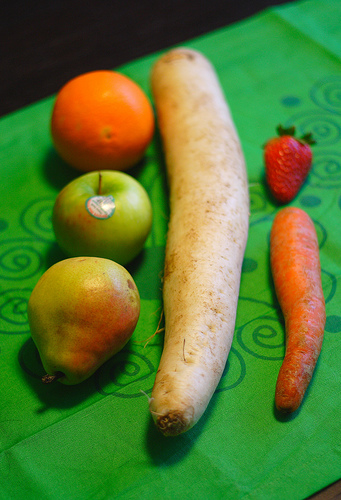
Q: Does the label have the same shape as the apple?
A: Yes, both the label and the apple are round.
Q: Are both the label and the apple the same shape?
A: Yes, both the label and the apple are round.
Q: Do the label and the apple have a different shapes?
A: No, both the label and the apple are round.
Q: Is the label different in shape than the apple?
A: No, both the label and the apple are round.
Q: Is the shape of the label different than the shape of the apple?
A: No, both the label and the apple are round.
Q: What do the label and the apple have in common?
A: The shape, both the label and the apple are round.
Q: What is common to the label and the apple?
A: The shape, both the label and the apple are round.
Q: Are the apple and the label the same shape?
A: Yes, both the apple and the label are round.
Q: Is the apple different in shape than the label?
A: No, both the apple and the label are round.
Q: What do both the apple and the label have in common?
A: The shape, both the apple and the label are round.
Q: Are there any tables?
A: Yes, there is a table.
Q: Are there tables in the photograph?
A: Yes, there is a table.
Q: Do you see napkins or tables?
A: Yes, there is a table.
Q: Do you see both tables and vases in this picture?
A: No, there is a table but no vases.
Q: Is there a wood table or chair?
A: Yes, there is a wood table.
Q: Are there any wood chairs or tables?
A: Yes, there is a wood table.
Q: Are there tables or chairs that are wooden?
A: Yes, the table is wooden.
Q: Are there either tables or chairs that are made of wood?
A: Yes, the table is made of wood.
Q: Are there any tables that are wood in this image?
A: Yes, there is a wood table.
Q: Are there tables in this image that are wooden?
A: Yes, there is a table that is wooden.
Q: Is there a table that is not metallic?
A: Yes, there is a wooden table.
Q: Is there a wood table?
A: Yes, there is a table that is made of wood.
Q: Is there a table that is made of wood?
A: Yes, there is a table that is made of wood.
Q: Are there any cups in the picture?
A: No, there are no cups.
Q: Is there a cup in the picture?
A: No, there are no cups.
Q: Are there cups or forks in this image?
A: No, there are no cups or forks.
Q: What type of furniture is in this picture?
A: The furniture is a table.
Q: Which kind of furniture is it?
A: The piece of furniture is a table.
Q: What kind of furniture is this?
A: This is a table.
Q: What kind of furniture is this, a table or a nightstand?
A: This is a table.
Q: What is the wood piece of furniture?
A: The piece of furniture is a table.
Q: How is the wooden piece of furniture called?
A: The piece of furniture is a table.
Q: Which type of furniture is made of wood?
A: The furniture is a table.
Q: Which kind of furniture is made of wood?
A: The furniture is a table.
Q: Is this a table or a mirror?
A: This is a table.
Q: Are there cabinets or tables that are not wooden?
A: No, there is a table but it is wooden.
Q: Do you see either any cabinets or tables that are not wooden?
A: No, there is a table but it is wooden.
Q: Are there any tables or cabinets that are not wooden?
A: No, there is a table but it is wooden.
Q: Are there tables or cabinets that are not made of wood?
A: No, there is a table but it is made of wood.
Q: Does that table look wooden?
A: Yes, the table is wooden.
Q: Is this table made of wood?
A: Yes, the table is made of wood.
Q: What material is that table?
A: The table is made of wood.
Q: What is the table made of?
A: The table is made of wood.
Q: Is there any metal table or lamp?
A: No, there is a table but it is wooden.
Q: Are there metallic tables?
A: No, there is a table but it is wooden.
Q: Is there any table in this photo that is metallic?
A: No, there is a table but it is wooden.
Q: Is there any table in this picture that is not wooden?
A: No, there is a table but it is wooden.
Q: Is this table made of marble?
A: No, the table is made of wood.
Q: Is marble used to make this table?
A: No, the table is made of wood.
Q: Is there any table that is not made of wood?
A: No, there is a table but it is made of wood.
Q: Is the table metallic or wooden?
A: The table is wooden.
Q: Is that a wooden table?
A: Yes, that is a wooden table.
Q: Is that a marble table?
A: No, that is a wooden table.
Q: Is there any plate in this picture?
A: No, there are no plates.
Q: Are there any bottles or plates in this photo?
A: No, there are no plates or bottles.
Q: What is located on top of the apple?
A: The label is on top of the apple.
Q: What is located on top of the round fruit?
A: The label is on top of the apple.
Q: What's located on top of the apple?
A: The label is on top of the apple.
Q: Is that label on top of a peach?
A: No, the label is on top of the apple.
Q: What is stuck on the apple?
A: The label is stuck on the apple.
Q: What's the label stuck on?
A: The label is stuck on the apple.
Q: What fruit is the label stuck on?
A: The label is stuck on the apple.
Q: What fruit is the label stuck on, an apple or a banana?
A: The label is stuck on an apple.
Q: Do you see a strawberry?
A: Yes, there is a strawberry.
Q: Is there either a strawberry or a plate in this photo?
A: Yes, there is a strawberry.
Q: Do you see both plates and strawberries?
A: No, there is a strawberry but no plates.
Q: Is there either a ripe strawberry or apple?
A: Yes, there is a ripe strawberry.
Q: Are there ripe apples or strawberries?
A: Yes, there is a ripe strawberry.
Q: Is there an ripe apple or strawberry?
A: Yes, there is a ripe strawberry.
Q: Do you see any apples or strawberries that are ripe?
A: Yes, the strawberry is ripe.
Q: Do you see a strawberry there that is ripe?
A: Yes, there is a ripe strawberry.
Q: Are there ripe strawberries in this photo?
A: Yes, there is a ripe strawberry.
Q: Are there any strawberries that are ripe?
A: Yes, there is a strawberry that is ripe.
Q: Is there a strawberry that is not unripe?
A: Yes, there is an ripe strawberry.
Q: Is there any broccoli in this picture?
A: No, there is no broccoli.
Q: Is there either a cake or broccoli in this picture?
A: No, there are no broccoli or cakes.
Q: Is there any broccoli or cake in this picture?
A: No, there are no broccoli or cakes.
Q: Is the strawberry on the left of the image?
A: No, the strawberry is on the right of the image.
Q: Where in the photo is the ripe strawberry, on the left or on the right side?
A: The strawberry is on the right of the image.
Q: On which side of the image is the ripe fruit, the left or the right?
A: The strawberry is on the right of the image.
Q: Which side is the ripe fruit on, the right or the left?
A: The strawberry is on the right of the image.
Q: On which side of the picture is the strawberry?
A: The strawberry is on the right of the image.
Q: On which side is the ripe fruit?
A: The strawberry is on the right of the image.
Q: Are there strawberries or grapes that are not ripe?
A: No, there is a strawberry but it is ripe.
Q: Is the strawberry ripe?
A: Yes, the strawberry is ripe.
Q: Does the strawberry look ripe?
A: Yes, the strawberry is ripe.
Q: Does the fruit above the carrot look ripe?
A: Yes, the strawberry is ripe.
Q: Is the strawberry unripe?
A: No, the strawberry is ripe.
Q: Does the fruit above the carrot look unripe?
A: No, the strawberry is ripe.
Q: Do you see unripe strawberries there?
A: No, there is a strawberry but it is ripe.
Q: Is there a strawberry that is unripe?
A: No, there is a strawberry but it is ripe.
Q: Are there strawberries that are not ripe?
A: No, there is a strawberry but it is ripe.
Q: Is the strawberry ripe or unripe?
A: The strawberry is ripe.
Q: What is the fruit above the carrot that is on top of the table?
A: The fruit is a strawberry.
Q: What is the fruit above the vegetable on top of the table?
A: The fruit is a strawberry.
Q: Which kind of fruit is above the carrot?
A: The fruit is a strawberry.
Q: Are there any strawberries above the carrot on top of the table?
A: Yes, there is a strawberry above the carrot.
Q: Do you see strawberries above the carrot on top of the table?
A: Yes, there is a strawberry above the carrot.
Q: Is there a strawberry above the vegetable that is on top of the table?
A: Yes, there is a strawberry above the carrot.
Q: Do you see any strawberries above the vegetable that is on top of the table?
A: Yes, there is a strawberry above the carrot.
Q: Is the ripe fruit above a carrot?
A: Yes, the strawberry is above a carrot.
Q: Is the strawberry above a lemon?
A: No, the strawberry is above a carrot.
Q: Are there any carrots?
A: Yes, there is a carrot.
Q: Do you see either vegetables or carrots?
A: Yes, there is a carrot.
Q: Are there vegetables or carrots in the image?
A: Yes, there is a carrot.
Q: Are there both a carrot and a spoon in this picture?
A: No, there is a carrot but no spoons.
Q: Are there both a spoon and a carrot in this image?
A: No, there is a carrot but no spoons.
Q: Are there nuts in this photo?
A: No, there are no nuts.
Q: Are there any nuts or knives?
A: No, there are no nuts or knives.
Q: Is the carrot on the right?
A: Yes, the carrot is on the right of the image.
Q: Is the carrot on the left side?
A: No, the carrot is on the right of the image.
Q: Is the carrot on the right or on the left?
A: The carrot is on the right of the image.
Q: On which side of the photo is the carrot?
A: The carrot is on the right of the image.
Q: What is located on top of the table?
A: The carrot is on top of the table.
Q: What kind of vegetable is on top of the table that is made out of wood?
A: The vegetable is a carrot.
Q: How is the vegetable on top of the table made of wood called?
A: The vegetable is a carrot.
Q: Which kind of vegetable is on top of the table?
A: The vegetable is a carrot.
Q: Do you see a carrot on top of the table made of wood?
A: Yes, there is a carrot on top of the table.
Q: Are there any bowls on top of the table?
A: No, there is a carrot on top of the table.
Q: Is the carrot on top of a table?
A: Yes, the carrot is on top of a table.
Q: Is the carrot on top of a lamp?
A: No, the carrot is on top of a table.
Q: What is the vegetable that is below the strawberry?
A: The vegetable is a carrot.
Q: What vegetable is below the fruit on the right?
A: The vegetable is a carrot.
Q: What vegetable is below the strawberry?
A: The vegetable is a carrot.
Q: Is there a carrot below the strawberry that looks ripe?
A: Yes, there is a carrot below the strawberry.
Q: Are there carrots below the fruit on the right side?
A: Yes, there is a carrot below the strawberry.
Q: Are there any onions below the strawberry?
A: No, there is a carrot below the strawberry.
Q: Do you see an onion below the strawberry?
A: No, there is a carrot below the strawberry.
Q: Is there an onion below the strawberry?
A: No, there is a carrot below the strawberry.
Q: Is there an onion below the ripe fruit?
A: No, there is a carrot below the strawberry.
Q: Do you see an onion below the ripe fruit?
A: No, there is a carrot below the strawberry.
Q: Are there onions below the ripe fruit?
A: No, there is a carrot below the strawberry.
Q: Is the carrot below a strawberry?
A: Yes, the carrot is below a strawberry.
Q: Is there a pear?
A: Yes, there is a pear.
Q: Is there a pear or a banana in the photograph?
A: Yes, there is a pear.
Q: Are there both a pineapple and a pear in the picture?
A: No, there is a pear but no pineapples.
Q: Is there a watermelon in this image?
A: No, there are no watermelons.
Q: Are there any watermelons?
A: No, there are no watermelons.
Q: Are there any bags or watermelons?
A: No, there are no watermelons or bags.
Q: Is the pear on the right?
A: No, the pear is on the left of the image.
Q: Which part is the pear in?
A: The pear is on the left of the image.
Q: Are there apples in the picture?
A: Yes, there is an apple.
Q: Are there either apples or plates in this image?
A: Yes, there is an apple.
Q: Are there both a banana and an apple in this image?
A: No, there is an apple but no bananas.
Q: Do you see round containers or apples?
A: Yes, there is a round apple.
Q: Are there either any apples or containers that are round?
A: Yes, the apple is round.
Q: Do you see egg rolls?
A: No, there are no egg rolls.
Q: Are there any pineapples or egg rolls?
A: No, there are no egg rolls or pineapples.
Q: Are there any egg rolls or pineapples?
A: No, there are no egg rolls or pineapples.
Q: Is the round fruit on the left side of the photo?
A: Yes, the apple is on the left of the image.